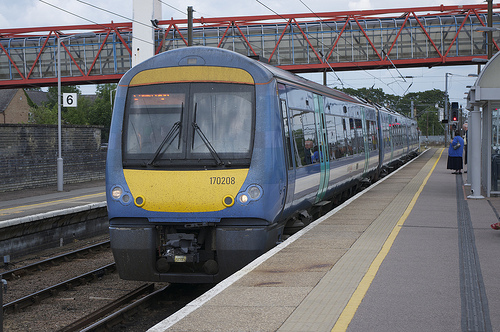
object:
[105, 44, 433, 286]
train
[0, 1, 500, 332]
train station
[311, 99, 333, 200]
double doors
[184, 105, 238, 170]
windshield wipers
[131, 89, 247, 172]
windshield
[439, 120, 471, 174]
woman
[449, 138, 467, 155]
blue shirt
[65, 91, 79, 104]
number 6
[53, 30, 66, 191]
pole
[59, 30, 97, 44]
lights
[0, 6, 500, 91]
bridge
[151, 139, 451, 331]
lines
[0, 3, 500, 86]
bars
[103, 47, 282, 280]
front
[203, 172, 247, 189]
number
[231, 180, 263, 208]
headlight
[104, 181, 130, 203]
headlight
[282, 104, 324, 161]
windows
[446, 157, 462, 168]
black skirt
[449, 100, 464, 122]
stoplight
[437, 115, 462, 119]
red light